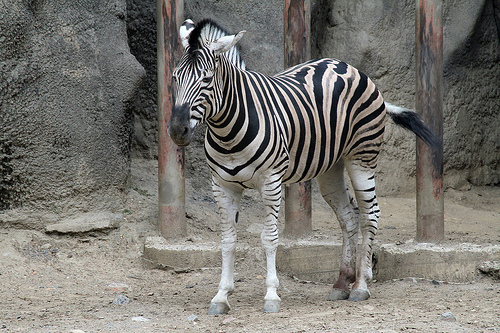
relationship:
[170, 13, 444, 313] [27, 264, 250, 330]
zebra standing on ground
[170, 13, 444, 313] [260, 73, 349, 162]
zebra has on stripes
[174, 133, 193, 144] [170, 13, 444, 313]
mouth of zebra